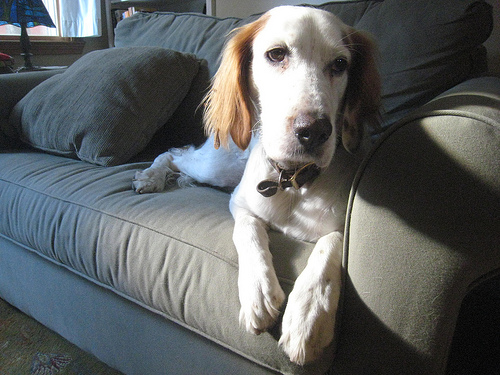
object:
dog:
[131, 3, 379, 363]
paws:
[236, 280, 285, 335]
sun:
[110, 194, 345, 356]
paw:
[277, 291, 338, 363]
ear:
[204, 20, 262, 150]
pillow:
[4, 48, 203, 168]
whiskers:
[332, 29, 362, 49]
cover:
[0, 0, 56, 28]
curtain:
[58, 0, 97, 37]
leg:
[282, 232, 341, 315]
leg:
[230, 209, 276, 283]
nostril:
[300, 130, 310, 138]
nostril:
[317, 134, 326, 140]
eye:
[265, 48, 286, 63]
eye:
[330, 57, 349, 72]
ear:
[340, 25, 381, 153]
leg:
[174, 132, 250, 187]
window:
[2, 0, 100, 35]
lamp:
[0, 0, 55, 71]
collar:
[257, 157, 320, 198]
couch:
[1, 0, 500, 375]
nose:
[293, 112, 332, 147]